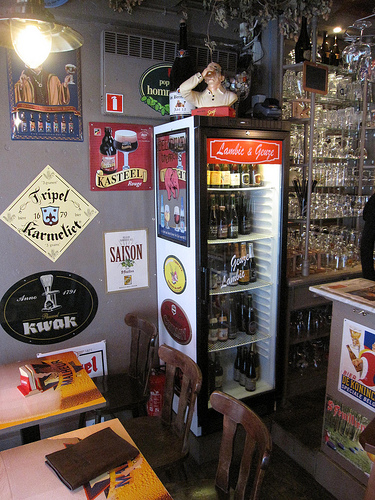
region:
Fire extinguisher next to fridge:
[140, 356, 163, 414]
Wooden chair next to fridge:
[86, 309, 156, 423]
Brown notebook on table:
[43, 421, 142, 491]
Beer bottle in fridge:
[226, 190, 239, 236]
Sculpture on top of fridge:
[176, 60, 239, 115]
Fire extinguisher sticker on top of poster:
[105, 92, 123, 111]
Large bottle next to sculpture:
[164, 13, 199, 119]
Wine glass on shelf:
[336, 133, 352, 156]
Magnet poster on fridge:
[160, 251, 187, 294]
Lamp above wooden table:
[0, 0, 86, 73]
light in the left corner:
[7, 3, 77, 62]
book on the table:
[39, 427, 148, 498]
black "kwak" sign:
[17, 262, 109, 354]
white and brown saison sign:
[105, 223, 153, 310]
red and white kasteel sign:
[88, 123, 163, 210]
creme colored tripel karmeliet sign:
[27, 180, 95, 265]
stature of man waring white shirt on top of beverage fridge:
[186, 53, 241, 126]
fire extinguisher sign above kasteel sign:
[102, 84, 129, 119]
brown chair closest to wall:
[119, 308, 171, 408]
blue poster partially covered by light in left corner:
[17, 41, 90, 154]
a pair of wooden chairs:
[164, 371, 271, 495]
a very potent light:
[2, 2, 79, 65]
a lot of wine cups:
[295, 128, 367, 274]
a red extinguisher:
[148, 363, 163, 418]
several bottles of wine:
[234, 345, 264, 389]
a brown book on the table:
[40, 427, 140, 487]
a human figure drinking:
[176, 63, 239, 115]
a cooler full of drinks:
[200, 192, 277, 389]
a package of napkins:
[19, 365, 42, 396]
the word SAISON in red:
[107, 242, 145, 263]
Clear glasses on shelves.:
[287, 77, 364, 277]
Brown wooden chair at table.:
[122, 337, 196, 488]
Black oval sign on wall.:
[1, 265, 99, 343]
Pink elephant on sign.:
[161, 165, 184, 209]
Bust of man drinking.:
[171, 59, 244, 116]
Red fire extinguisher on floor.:
[141, 358, 171, 422]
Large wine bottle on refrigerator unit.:
[165, 16, 195, 114]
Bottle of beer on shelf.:
[227, 192, 239, 237]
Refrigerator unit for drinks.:
[153, 118, 275, 428]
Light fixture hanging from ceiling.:
[0, 1, 87, 71]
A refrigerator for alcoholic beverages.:
[153, 108, 291, 427]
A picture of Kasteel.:
[85, 114, 153, 192]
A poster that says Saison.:
[102, 217, 151, 293]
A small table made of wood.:
[1, 411, 155, 496]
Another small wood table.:
[0, 343, 122, 429]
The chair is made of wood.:
[166, 388, 290, 496]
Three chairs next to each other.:
[88, 306, 275, 496]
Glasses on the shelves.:
[289, 64, 360, 270]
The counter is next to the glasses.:
[309, 272, 372, 489]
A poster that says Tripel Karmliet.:
[0, 163, 102, 262]